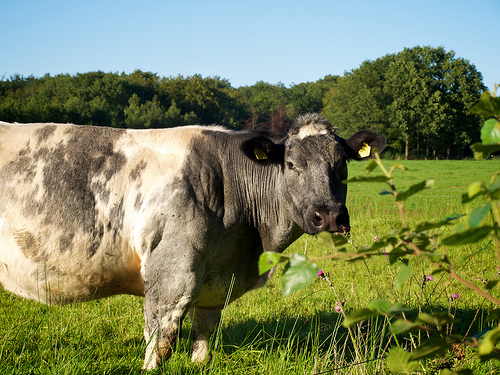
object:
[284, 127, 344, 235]
face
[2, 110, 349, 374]
cow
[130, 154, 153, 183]
spot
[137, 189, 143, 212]
spot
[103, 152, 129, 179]
spot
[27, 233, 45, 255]
spot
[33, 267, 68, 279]
spot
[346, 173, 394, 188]
leaf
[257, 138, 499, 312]
branch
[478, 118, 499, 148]
leaf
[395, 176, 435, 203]
leaf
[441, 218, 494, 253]
leaf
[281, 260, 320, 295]
leaf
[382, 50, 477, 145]
tree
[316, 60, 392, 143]
tree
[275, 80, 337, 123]
tree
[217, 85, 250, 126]
tree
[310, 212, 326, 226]
nostril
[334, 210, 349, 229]
nostril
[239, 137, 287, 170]
right ear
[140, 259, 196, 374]
leg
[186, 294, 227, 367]
leg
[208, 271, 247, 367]
grass leaf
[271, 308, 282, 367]
grass leaf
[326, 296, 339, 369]
grass leaf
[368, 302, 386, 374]
grass leaf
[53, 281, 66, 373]
grass leaf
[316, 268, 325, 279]
flower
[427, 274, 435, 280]
flower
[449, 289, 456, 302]
flower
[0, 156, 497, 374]
meadow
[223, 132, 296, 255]
neck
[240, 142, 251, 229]
wrinkle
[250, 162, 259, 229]
wrinkle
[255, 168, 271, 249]
wrinkle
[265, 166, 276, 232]
wrinkle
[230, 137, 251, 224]
wrinkle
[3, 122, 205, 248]
back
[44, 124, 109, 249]
marking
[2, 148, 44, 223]
marking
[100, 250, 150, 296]
rusty colored patch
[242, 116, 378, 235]
head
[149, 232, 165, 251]
indentation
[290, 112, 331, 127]
hair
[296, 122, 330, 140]
crown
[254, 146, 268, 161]
tag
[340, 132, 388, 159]
left ear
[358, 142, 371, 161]
tag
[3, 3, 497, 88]
sky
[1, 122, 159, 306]
torso